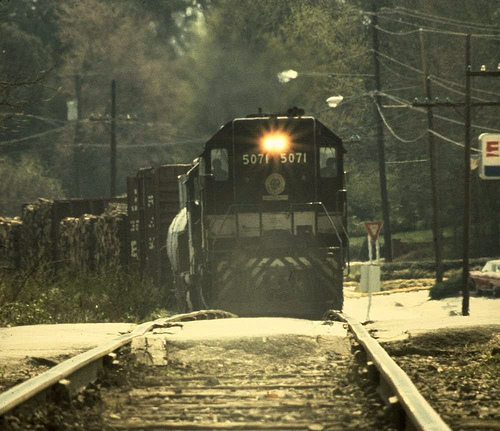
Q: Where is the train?
A: On the tracks.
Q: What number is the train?
A: 5071.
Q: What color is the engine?
A: Black.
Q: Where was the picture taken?
A: On a train track.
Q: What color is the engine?
A: Black.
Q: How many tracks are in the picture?
A: 1.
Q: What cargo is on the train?
A: Wood.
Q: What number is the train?
A: 5071.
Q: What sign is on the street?
A: Yield sign.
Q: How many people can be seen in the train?
A: 2.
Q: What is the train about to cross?
A: A street.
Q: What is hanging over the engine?
A: Street lights.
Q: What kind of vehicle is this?
A: Train.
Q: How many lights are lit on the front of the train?
A: One.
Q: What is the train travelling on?
A: Train tracks.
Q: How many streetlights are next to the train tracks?
A: Two.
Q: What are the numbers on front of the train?
A: 5071 5071.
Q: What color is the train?
A: Black.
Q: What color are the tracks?
A: Silver.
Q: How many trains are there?
A: One.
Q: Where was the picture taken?
A: The train tracks.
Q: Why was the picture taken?
A: To depict the train.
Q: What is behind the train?
A: Wood.